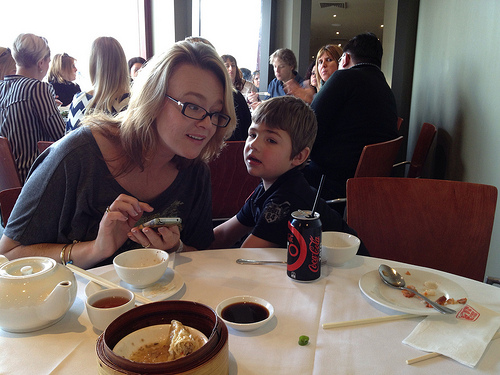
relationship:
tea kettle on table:
[0, 256, 76, 334] [168, 231, 432, 373]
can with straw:
[287, 209, 322, 282] [295, 157, 347, 222]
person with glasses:
[0, 41, 238, 272] [166, 87, 233, 127]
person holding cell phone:
[0, 41, 238, 272] [137, 217, 183, 236]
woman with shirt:
[4, 31, 70, 183] [1, 74, 69, 175]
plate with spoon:
[357, 260, 484, 325] [358, 252, 479, 334]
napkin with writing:
[408, 329, 470, 369] [456, 304, 485, 326]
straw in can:
[294, 170, 336, 218] [287, 209, 322, 283]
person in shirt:
[64, 37, 130, 135] [69, 79, 132, 128]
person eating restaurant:
[307, 26, 402, 198] [6, 0, 498, 372]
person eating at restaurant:
[0, 39, 239, 266] [6, 0, 498, 372]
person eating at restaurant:
[62, 29, 164, 109] [6, 0, 498, 372]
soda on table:
[285, 209, 320, 282] [0, 247, 497, 372]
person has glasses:
[0, 41, 238, 272] [162, 92, 234, 132]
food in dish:
[126, 324, 209, 371] [100, 297, 242, 373]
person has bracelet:
[0, 41, 238, 272] [51, 239, 99, 253]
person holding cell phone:
[0, 41, 238, 272] [141, 212, 185, 228]